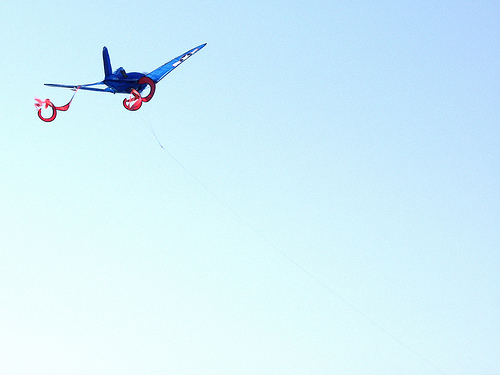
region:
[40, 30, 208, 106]
blue airplane in very clear blue sky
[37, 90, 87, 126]
red banner on airplane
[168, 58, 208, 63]
white paint on airplane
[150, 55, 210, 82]
blue wing on plane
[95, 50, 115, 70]
fin of blue tale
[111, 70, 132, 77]
cockpit of airplane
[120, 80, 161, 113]
red flag on plane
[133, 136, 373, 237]
blue and white skies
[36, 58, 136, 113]
left wing of plane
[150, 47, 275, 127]
right wing of plane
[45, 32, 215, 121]
blue airplane with red flags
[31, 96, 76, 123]
red flag hanging from airplane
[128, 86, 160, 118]
red flag hanging from airplane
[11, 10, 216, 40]
white clouds against blue sky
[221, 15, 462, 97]
white clouds against blue sky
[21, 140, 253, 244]
white clouds against blue sky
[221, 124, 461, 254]
white clouds against blue sky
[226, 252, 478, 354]
white clouds against blue sky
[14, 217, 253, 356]
white clouds against blue sky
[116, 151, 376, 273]
white clouds against blue sky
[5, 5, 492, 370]
The sky is blue.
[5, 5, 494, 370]
the sky is clear.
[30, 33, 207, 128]
Kite is in the sky.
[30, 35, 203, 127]
The kite is red, white and blue.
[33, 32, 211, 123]
Only one kite flying.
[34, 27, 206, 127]
Kite is an airplane.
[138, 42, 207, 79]
The wing is blue.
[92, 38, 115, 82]
The tail is blue.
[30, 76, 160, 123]
Ribbons are red.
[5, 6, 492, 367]
Kite is flying during the day.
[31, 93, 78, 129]
red flag hanging from blue airplane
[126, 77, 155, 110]
red flag hanging from blue airplane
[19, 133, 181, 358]
white clouds against blue sky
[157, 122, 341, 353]
white clouds against blue sky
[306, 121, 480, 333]
white clouds against blue sky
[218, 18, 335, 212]
white clouds against blue sky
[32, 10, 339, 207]
a kite in the air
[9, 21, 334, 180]
an airplane shaped kite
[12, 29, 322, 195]
a kite with red tails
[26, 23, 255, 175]
a blue kite flying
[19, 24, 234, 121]
a blue kite in the air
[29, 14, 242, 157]
a blue airplane kite in the sky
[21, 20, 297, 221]
a blue airplane kite flying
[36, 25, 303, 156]
a blue airplane kite with red tails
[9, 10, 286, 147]
red blue kite flying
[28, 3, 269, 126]
airplane kite that is red and blue